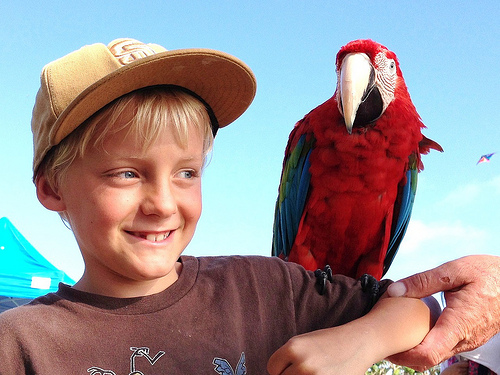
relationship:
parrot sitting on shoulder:
[271, 37, 445, 304] [233, 255, 319, 337]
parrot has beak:
[271, 37, 445, 304] [338, 51, 383, 135]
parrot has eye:
[271, 37, 445, 304] [389, 61, 395, 71]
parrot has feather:
[271, 37, 445, 304] [418, 134, 444, 155]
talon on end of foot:
[320, 277, 327, 295] [312, 263, 333, 296]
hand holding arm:
[382, 253, 499, 372] [272, 256, 442, 358]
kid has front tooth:
[0, 37, 442, 375] [156, 234, 165, 242]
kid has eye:
[0, 37, 442, 375] [173, 169, 192, 179]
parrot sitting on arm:
[271, 37, 445, 304] [272, 256, 442, 358]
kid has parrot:
[0, 37, 442, 375] [271, 37, 445, 304]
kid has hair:
[0, 37, 442, 375] [32, 84, 214, 230]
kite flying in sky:
[476, 152, 497, 166] [1, 0, 499, 282]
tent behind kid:
[0, 216, 78, 314] [0, 37, 442, 375]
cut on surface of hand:
[454, 258, 497, 281] [382, 253, 499, 372]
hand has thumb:
[382, 253, 499, 372] [386, 256, 474, 299]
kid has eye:
[0, 37, 442, 375] [105, 170, 141, 180]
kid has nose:
[0, 37, 442, 375] [140, 175, 178, 219]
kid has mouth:
[0, 37, 442, 375] [121, 224, 182, 249]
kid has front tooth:
[0, 37, 442, 375] [145, 234, 156, 242]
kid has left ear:
[0, 37, 442, 375] [36, 173, 66, 211]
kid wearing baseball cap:
[0, 37, 442, 375] [29, 37, 259, 184]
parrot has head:
[271, 37, 445, 304] [334, 39, 410, 136]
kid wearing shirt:
[0, 37, 442, 375] [0, 255, 396, 375]